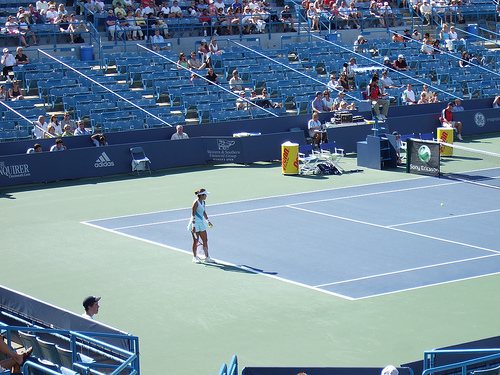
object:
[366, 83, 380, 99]
red jacket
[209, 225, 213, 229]
tennis ball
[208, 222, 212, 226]
hand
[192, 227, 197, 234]
hand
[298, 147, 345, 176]
chairs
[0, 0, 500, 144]
stands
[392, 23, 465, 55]
spectators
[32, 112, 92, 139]
spectators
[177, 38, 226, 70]
spectators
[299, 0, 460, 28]
spectators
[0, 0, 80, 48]
spectators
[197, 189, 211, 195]
cap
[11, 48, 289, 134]
seats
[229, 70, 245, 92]
person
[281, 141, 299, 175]
drink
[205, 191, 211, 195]
sun visor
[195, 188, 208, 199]
head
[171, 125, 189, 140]
person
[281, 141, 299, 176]
can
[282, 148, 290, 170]
letters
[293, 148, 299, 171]
letters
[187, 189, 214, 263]
box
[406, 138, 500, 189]
net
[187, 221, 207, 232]
dress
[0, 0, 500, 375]
court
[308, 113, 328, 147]
person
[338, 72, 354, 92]
person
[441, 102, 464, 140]
person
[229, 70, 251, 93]
person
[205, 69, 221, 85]
person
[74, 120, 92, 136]
person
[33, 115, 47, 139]
person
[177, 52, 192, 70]
person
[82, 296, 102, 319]
boy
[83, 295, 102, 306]
cap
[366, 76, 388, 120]
man